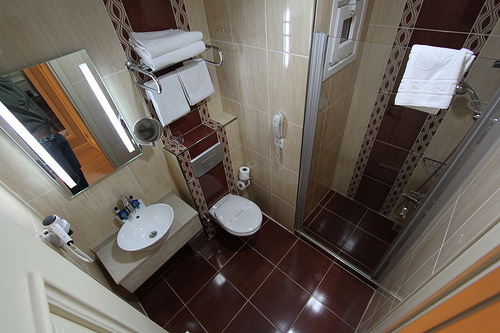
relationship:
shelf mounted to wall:
[124, 44, 224, 95] [73, 6, 292, 197]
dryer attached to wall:
[35, 212, 98, 266] [0, 171, 118, 285]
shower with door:
[289, 1, 499, 286] [293, 30, 498, 280]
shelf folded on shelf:
[124, 44, 224, 95] [113, 18, 229, 96]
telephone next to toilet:
[269, 110, 286, 165] [207, 186, 264, 236]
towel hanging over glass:
[393, 44, 477, 115] [301, 32, 473, 331]